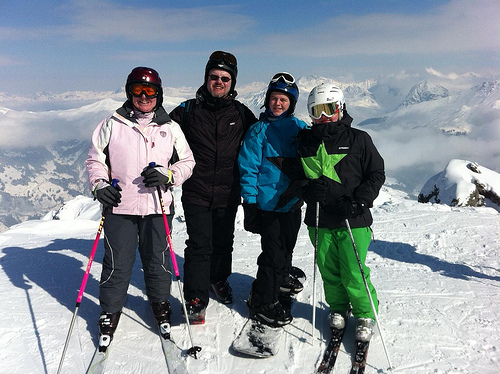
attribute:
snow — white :
[0, 192, 497, 372]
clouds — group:
[361, 120, 491, 200]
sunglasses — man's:
[208, 72, 231, 84]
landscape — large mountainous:
[0, 0, 498, 225]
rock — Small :
[414, 158, 499, 208]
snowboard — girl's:
[216, 268, 328, 369]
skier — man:
[46, 247, 387, 372]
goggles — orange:
[130, 87, 160, 99]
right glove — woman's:
[91, 181, 122, 207]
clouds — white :
[0, 1, 497, 83]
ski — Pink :
[323, 285, 460, 374]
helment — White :
[301, 81, 347, 117]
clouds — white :
[13, 9, 488, 49]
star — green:
[299, 141, 344, 188]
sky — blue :
[2, 1, 498, 97]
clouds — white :
[84, 7, 245, 39]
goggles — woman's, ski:
[123, 78, 160, 100]